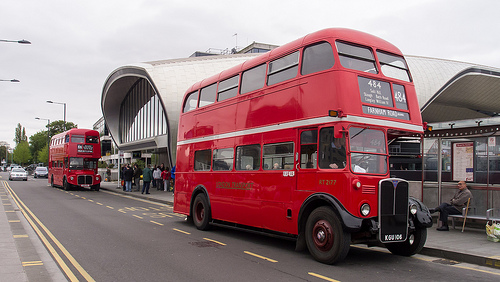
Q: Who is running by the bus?
A: No one.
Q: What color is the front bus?
A: Red.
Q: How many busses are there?
A: Two.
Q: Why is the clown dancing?
A: No clown.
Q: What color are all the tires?
A: Black.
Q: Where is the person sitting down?
A: Beside first bus.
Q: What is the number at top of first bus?
A: 484.